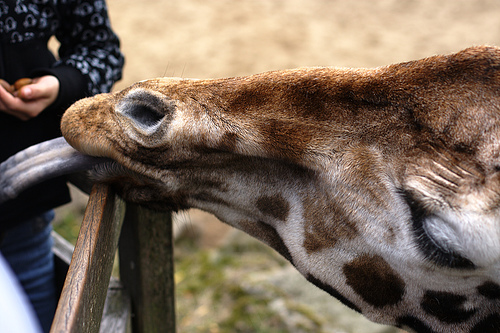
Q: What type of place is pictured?
A: It is a zoo.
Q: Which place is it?
A: It is a zoo.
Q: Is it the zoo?
A: Yes, it is the zoo.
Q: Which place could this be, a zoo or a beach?
A: It is a zoo.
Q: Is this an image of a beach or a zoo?
A: It is showing a zoo.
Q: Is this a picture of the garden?
A: No, the picture is showing the zoo.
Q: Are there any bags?
A: No, there are no bags.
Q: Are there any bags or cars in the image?
A: No, there are no bags or cars.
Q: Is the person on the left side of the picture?
A: Yes, the person is on the left of the image.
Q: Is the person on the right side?
A: No, the person is on the left of the image.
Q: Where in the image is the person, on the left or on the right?
A: The person is on the left of the image.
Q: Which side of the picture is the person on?
A: The person is on the left of the image.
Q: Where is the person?
A: The person is at the zoo.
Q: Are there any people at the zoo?
A: Yes, there is a person at the zoo.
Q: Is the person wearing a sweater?
A: Yes, the person is wearing a sweater.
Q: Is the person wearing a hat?
A: No, the person is wearing a sweater.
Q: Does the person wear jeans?
A: Yes, the person wears jeans.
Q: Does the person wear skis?
A: No, the person wears jeans.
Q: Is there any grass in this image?
A: Yes, there is grass.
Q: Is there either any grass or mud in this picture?
A: Yes, there is grass.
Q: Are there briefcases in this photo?
A: No, there are no briefcases.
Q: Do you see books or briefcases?
A: No, there are no briefcases or books.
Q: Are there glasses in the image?
A: No, there are no glasses.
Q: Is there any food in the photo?
A: Yes, there is food.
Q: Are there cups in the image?
A: No, there are no cups.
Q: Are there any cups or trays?
A: No, there are no cups or trays.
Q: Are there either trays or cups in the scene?
A: No, there are no cups or trays.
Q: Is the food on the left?
A: Yes, the food is on the left of the image.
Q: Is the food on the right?
A: No, the food is on the left of the image.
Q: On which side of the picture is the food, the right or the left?
A: The food is on the left of the image.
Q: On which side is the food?
A: The food is on the left of the image.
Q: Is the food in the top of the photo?
A: Yes, the food is in the top of the image.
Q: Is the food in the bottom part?
A: No, the food is in the top of the image.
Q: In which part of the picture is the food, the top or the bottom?
A: The food is in the top of the image.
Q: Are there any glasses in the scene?
A: No, there are no glasses.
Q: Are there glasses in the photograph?
A: No, there are no glasses.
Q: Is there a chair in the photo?
A: No, there are no chairs.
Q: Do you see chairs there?
A: No, there are no chairs.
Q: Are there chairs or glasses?
A: No, there are no chairs or glasses.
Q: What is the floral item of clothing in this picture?
A: The clothing item is a sweater.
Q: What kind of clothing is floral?
A: The clothing is a sweater.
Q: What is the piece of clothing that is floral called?
A: The clothing item is a sweater.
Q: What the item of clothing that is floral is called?
A: The clothing item is a sweater.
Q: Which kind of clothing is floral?
A: The clothing is a sweater.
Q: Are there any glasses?
A: No, there are no glasses.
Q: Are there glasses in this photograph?
A: No, there are no glasses.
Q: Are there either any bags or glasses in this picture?
A: No, there are no glasses or bags.